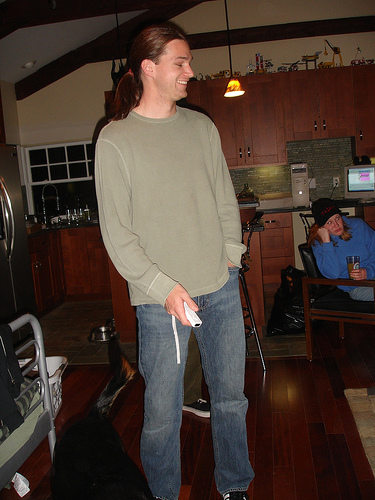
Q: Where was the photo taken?
A: In a kitchen.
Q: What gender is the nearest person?
A: Male.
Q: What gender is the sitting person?
A: Female.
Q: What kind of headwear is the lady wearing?
A: A winter hat.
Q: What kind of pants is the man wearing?
A: Jeans.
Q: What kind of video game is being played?
A: Wii.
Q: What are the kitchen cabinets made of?
A: Wood.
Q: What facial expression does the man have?
A: A smile.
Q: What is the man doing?
A: Playing Wii.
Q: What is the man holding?
A: A Wii controller.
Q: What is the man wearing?
A: A green shirt.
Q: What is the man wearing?
A: Jeans.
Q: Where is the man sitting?
A: In a black chair.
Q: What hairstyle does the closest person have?
A: Ponytail.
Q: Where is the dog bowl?
A: On the floor.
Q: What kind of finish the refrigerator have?
A: Stainless steel.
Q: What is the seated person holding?
A: A glass.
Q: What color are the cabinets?
A: Brown.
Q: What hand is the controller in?
A: Right.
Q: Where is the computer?
A: On counter.